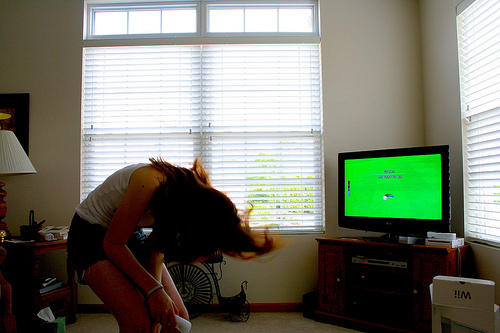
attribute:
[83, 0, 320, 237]
window — large, doubel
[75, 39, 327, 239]
blinds — mini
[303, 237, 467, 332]
stand — brown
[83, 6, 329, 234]
blinds — white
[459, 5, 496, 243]
blinds — white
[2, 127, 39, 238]
lamp — white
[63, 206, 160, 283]
shorts — black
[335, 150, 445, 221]
screen — green